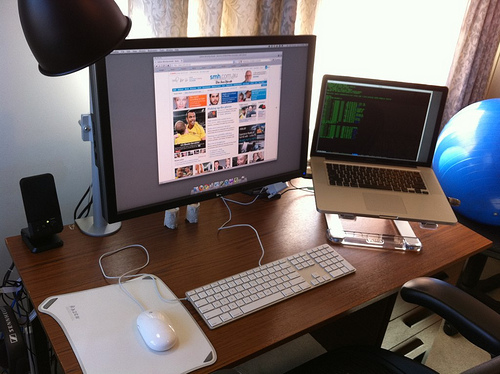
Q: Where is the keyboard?
A: On desk.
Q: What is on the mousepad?
A: A mouse.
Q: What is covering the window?
A: Curtains.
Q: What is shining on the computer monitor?
A: A lamp.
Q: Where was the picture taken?
A: In office.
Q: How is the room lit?
A: Sunlight.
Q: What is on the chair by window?
A: A ball.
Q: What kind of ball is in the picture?
A: A yoga ball.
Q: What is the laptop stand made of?
A: Plastic.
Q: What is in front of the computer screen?
A: A keyboard.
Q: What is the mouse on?
A: A mouse pad.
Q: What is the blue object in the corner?
A: A blue exercise ball.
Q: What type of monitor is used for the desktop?
A: A flat screen monitor.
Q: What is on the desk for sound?
A: A speaker.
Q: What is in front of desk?
A: A desk chair.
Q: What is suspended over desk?
A: A light.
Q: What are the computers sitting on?
A: Desk.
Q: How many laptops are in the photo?
A: One.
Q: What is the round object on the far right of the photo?
A: Blue ball.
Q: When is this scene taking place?
A: Daytime.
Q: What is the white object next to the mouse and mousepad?
A: Computer keyboard.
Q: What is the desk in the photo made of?
A: Wood.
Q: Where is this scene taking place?
A: In an office.